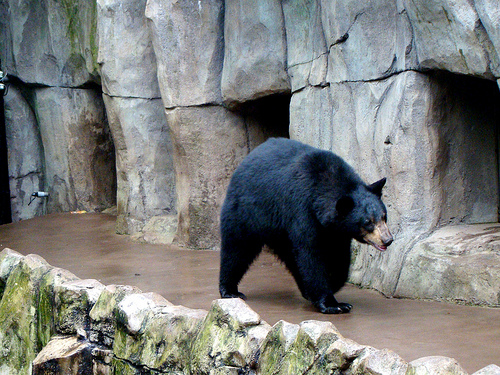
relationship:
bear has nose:
[218, 138, 395, 315] [380, 231, 392, 246]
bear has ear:
[218, 138, 395, 315] [335, 197, 355, 219]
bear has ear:
[218, 138, 395, 315] [366, 176, 387, 199]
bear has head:
[218, 138, 395, 315] [316, 180, 393, 251]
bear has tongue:
[218, 138, 395, 315] [376, 243, 390, 249]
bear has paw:
[218, 138, 395, 315] [218, 288, 246, 301]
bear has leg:
[218, 138, 395, 315] [220, 224, 264, 287]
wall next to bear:
[4, 2, 499, 309] [218, 138, 395, 315]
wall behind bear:
[4, 2, 499, 309] [218, 138, 395, 315]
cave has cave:
[421, 71, 500, 267] [421, 71, 500, 241]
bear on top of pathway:
[218, 138, 395, 315] [0, 211, 500, 372]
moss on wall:
[62, 1, 100, 65] [4, 2, 499, 309]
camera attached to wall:
[29, 190, 49, 208] [4, 2, 499, 309]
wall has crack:
[4, 2, 499, 309] [285, 8, 368, 71]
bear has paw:
[218, 138, 395, 315] [314, 302, 342, 313]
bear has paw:
[218, 138, 395, 315] [329, 300, 354, 310]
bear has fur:
[218, 138, 395, 315] [219, 138, 386, 314]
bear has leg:
[218, 138, 395, 315] [274, 236, 343, 317]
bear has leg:
[218, 138, 395, 315] [316, 229, 355, 312]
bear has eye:
[218, 138, 395, 315] [365, 218, 373, 227]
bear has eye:
[218, 138, 395, 315] [381, 211, 386, 221]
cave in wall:
[421, 71, 500, 241] [4, 2, 499, 309]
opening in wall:
[240, 94, 289, 162] [4, 2, 499, 309]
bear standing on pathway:
[218, 138, 395, 315] [0, 211, 500, 372]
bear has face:
[218, 138, 395, 315] [335, 178, 397, 253]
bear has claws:
[218, 138, 395, 315] [337, 303, 355, 312]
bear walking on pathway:
[218, 138, 395, 315] [0, 211, 500, 372]